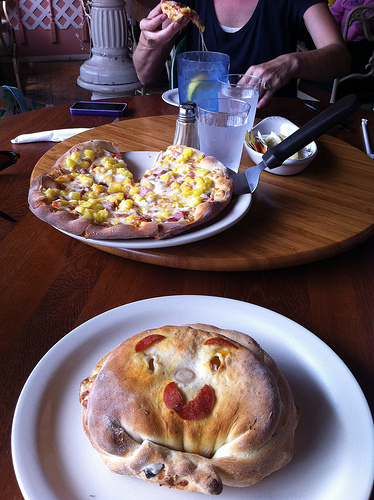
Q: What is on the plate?
A: A small pizza.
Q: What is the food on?
A: A small round and white plate.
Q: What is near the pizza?
A: A spatula.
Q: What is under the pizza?
A: A spatula.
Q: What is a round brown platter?
A: A plate.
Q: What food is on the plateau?
A: Pizza.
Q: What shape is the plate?
A: Circle.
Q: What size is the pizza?
A: Personal.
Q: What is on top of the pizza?
A: Pineapple.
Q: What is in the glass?
A: Water.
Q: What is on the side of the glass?
A: Lemon.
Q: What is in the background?
A: Pole.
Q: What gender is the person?
A: Female.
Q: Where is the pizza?
A: On the white plate.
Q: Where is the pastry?
A: On a white plate.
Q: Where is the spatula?
A: Under the pizza.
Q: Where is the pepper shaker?
A: By the pizza.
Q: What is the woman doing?
A: Eating pizza.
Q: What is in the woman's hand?
A: Slice of pizza.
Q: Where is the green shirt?
A: On the woman.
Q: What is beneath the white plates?
A: A wooden table.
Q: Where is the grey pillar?
A: Behind the table.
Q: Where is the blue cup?
A: By the woman.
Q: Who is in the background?
A: Lady.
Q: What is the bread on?
A: Plate.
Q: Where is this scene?
A: Restaurant.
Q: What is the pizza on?
A: Tray.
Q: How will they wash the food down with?
A: Water.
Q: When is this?
A: Time to eat.